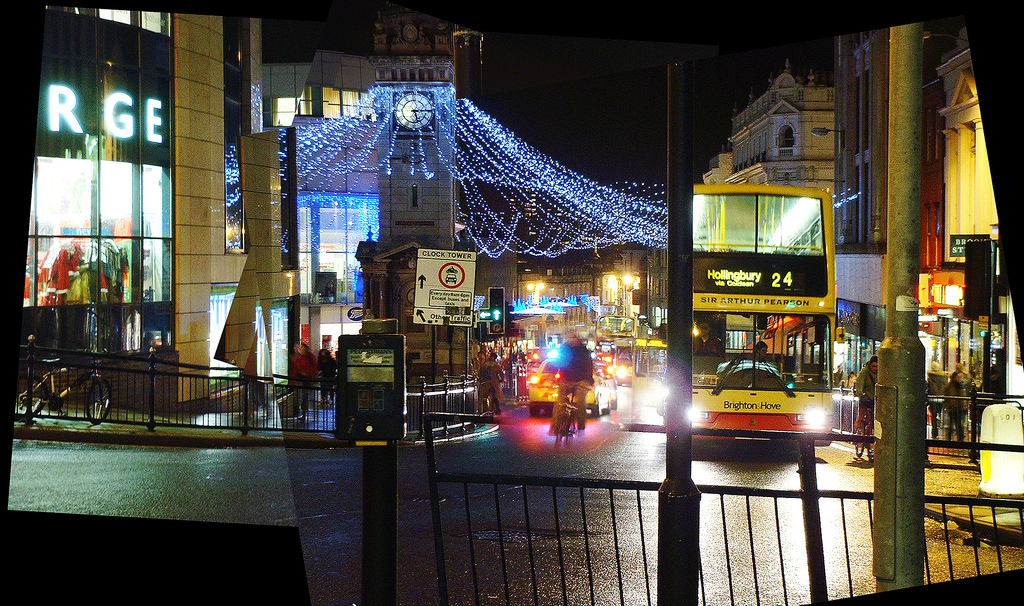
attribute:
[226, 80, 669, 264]
blue lights — above ground